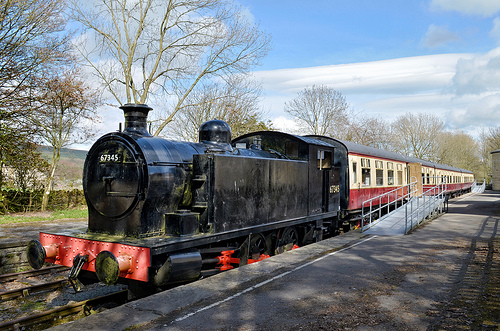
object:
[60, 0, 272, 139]
tree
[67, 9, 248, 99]
branch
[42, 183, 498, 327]
platform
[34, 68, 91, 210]
tree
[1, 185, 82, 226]
field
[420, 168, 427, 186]
windows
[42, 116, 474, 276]
train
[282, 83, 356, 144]
tree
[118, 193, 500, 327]
concrete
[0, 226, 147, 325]
rail track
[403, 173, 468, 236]
rail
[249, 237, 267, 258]
wheel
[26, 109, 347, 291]
locomotive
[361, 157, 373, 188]
window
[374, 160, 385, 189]
window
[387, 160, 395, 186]
window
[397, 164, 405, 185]
window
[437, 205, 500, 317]
tracks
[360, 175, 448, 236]
ramp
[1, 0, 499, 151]
sky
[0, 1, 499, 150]
clouds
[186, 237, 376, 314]
line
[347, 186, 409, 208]
car bottom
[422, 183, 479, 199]
car bottom